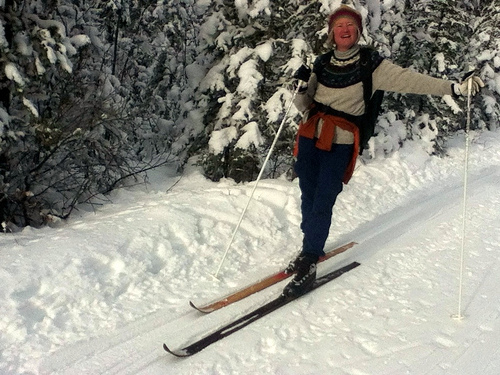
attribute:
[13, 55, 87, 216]
trees — side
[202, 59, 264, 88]
snow — white, pile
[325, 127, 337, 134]
sweater — orange, tied, grey, gray, black, wrapped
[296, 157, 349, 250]
pants — blue, dark, long, black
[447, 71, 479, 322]
ski pole — here, white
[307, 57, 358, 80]
scarf — black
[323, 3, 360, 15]
hat — red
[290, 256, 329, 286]
boots — black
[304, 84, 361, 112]
shirt — tan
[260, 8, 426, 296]
woman — skiing, old, leaning